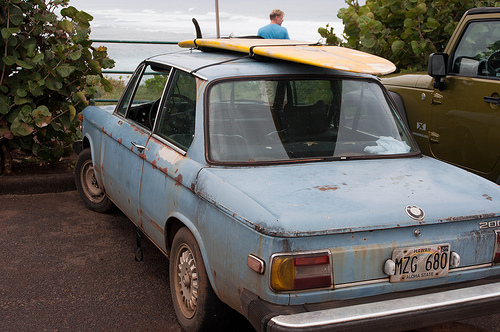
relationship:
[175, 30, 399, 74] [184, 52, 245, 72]
surfboard tied to roof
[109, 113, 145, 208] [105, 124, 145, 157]
door has rust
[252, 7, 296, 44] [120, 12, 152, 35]
man watching ocean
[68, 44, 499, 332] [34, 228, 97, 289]
bmw in parking lot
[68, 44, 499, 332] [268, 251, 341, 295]
bmw has backlights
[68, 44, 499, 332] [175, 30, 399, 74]
bmw has surfboard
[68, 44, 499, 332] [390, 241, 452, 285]
bmw has license plate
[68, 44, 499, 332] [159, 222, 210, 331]
bmw has back tire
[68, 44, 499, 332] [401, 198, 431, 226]
bmw has logo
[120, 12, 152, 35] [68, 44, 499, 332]
ocean by bmw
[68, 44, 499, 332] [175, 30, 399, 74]
bmw with surfboard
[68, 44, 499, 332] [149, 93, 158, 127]
bmw has wheel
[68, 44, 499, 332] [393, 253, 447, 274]
bmw has plate number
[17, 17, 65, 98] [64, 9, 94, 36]
plant has leaves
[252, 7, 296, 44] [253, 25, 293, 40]
person wearing shirt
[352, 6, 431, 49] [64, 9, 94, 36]
tree has leaves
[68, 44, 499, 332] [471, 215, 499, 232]
bmw has number plates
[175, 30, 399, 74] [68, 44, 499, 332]
surfboard on top of bmw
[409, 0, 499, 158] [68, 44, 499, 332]
jeep parked next to bmw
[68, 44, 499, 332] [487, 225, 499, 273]
bmw has a tail light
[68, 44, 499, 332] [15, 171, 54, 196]
bmw parked at curb